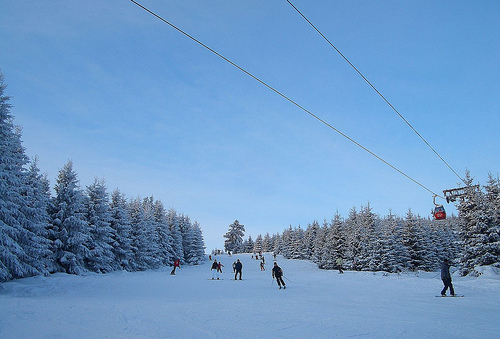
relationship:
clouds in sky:
[3, 1, 499, 252] [1, 0, 500, 254]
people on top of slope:
[169, 250, 464, 298] [0, 251, 499, 338]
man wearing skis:
[270, 261, 288, 290] [276, 284, 288, 291]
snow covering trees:
[1, 70, 500, 338] [1, 71, 500, 285]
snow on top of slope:
[1, 70, 500, 338] [0, 251, 500, 339]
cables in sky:
[131, 1, 469, 198] [1, 0, 500, 254]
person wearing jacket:
[169, 256, 182, 277] [174, 259, 181, 269]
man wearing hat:
[270, 261, 288, 290] [271, 260, 279, 264]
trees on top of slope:
[1, 71, 500, 285] [0, 251, 499, 338]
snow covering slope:
[1, 70, 500, 338] [0, 251, 500, 339]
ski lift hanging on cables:
[432, 191, 447, 222] [131, 1, 469, 198]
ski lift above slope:
[432, 191, 447, 222] [0, 251, 499, 338]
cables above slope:
[131, 1, 469, 198] [0, 251, 499, 338]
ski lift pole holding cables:
[443, 183, 484, 205] [131, 1, 469, 198]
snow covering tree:
[0, 71, 51, 282] [0, 72, 50, 284]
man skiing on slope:
[270, 261, 288, 290] [0, 251, 499, 338]